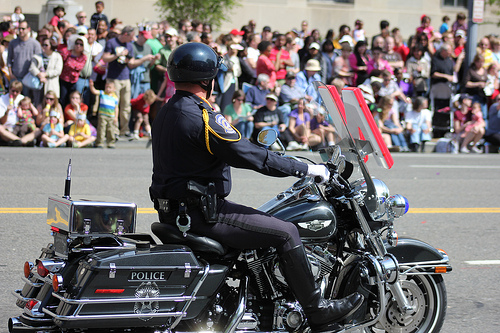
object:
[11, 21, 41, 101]
man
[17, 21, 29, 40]
head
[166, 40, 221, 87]
helmet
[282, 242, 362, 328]
boot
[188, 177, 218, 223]
gun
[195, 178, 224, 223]
holster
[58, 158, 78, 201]
antenna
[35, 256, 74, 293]
signal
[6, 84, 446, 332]
motorcycle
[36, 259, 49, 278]
light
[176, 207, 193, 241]
handcuffs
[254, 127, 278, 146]
mirror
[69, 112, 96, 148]
boy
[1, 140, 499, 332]
street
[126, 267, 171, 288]
police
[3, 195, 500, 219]
line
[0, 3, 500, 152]
crowd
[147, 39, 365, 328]
officer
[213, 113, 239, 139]
emblem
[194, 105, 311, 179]
sleeve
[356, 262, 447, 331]
tire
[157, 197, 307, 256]
pants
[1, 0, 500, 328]
image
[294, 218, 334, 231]
logo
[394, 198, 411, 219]
light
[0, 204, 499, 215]
stripe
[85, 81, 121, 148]
children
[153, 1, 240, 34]
tree